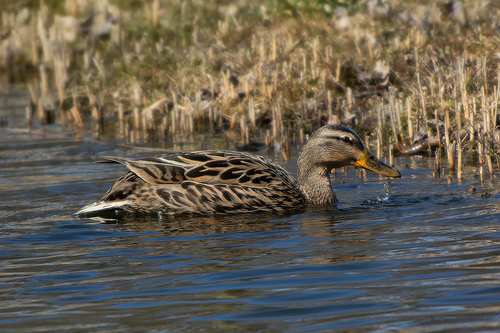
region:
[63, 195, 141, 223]
Tail of swimming duck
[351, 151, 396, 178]
Orange beak of duck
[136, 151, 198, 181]
Feathers of swimming duck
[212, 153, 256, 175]
Part of swimming duck's feathers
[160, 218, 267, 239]
Reflection of swimming duck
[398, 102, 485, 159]
part of grass reeds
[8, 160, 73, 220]
part of blue rippled water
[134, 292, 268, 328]
part of blue rippled water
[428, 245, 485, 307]
Part of rippled blue water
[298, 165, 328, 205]
Part of swimming duck's head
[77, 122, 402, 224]
brown duck swimming in water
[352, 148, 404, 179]
orange bill on face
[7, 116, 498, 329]
dark murky water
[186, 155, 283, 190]
black outline on feathers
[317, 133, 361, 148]
black stripe around eye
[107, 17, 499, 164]
dead grass on shore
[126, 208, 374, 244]
reflection of duck in water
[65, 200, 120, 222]
white feathers on tail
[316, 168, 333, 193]
bumps on neck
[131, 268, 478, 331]
ripples in water from duck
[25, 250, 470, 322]
the water is dark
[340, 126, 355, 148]
the eye is black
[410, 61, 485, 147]
the grass is brown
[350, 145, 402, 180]
the bill is orange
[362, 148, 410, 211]
water is coming out of the ducks bill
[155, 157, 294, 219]
the duck has feathers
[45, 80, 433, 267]
the duck is in the water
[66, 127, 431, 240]
the duck is brown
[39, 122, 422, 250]
the duck is black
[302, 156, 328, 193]
the duck has a neck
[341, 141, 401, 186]
peak of duck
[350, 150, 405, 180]
peak of duck is yellow and black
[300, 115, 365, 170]
head is gray with black stripes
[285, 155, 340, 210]
neck of duck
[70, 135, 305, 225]
body of duck is brown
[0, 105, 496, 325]
a duck in the water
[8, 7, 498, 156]
dry plants in the water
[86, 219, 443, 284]
reflections on the water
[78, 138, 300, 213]
black spots on feathers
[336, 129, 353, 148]
eye of duck is black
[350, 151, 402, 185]
The beak is orange.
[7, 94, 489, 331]
The water is calm.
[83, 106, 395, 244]
The duck is in the water.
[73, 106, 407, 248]
The duck is brown.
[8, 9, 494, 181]
The grass is brown.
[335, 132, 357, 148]
His eye is black.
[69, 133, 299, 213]
His feathers are light and dark brown.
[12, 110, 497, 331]
The water is blue.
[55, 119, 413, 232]
The water is swimming.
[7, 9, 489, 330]
The sun is shining.